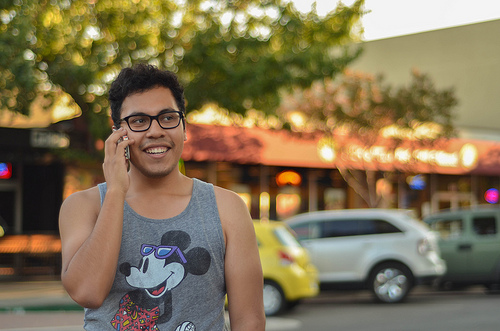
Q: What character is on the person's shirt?
A: Mickey mouse.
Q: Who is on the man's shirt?
A: Mickey Mouse.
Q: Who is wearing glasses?
A: The man.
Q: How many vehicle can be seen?
A: Three.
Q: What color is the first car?
A: Yellow.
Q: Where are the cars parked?
A: In front of the building.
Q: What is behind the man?
A: A tree.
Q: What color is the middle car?
A: White.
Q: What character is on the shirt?
A: Mickey Mouse.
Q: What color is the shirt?
A: Grey.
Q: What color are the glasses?
A: Black.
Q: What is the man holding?
A: Cell phone.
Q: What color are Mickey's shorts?
A: Red.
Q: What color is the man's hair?
A: Black.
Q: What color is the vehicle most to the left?
A: Yellow.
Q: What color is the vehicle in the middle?
A: White.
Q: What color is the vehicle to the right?
A: Grey.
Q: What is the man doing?
A: Talking on the phone.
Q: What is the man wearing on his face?
A: Glasses.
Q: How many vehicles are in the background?
A: Three.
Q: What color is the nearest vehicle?
A: Yellow.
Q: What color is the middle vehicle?
A: White.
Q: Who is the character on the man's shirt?
A: Mickey Mouse.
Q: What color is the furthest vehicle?
A: Green.